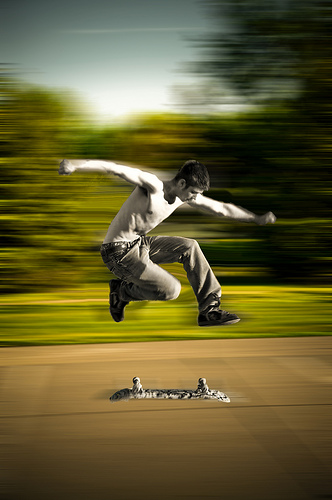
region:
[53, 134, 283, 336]
A male athlete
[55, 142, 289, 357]
A male jumping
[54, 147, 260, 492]
A skateboarder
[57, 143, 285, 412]
A skateboarder doing a trick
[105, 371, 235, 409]
A skateboard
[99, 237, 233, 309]
The jeans the man is wearing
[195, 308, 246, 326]
The left foot of the man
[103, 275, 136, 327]
The right foot of the man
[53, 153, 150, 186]
The right arm of the man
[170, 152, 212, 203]
The head of the skateboarder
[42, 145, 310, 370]
this is a unique photo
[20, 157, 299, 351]
the background makes this picture look alive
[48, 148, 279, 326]
this young man is posing over a skateboard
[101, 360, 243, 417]
the skateboard is turned upside down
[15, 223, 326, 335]
green and yellow scenery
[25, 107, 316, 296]
the green and yellow streaks are grass and trees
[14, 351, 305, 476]
this brown area is the ground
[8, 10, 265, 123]
this part of the photo is the sky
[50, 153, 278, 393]
this skateboarder is not wearing a shirt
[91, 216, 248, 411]
he is doing stunt tricks on his skateboard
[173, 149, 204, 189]
boy has dark hair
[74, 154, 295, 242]
boy has arms extended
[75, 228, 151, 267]
boy wears black belt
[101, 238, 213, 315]
boy is wearing jeans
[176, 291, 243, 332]
boy wears dark shoes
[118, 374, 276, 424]
boy jumps off skateboard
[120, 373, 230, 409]
skateboard is upside down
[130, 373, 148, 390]
skateboard has light colored wheels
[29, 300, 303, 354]
green grass behind boy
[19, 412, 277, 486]
brown dirt under skateboard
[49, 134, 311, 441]
a skateboarder in the air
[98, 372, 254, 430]
an upside down skateboard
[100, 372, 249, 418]
a black and white skateboard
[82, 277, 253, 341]
black shoes worn by skatboarder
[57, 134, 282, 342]
a guy with no shirt on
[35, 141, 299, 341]
a guy doing tricks on a skateboard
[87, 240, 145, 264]
a black belt on his jeans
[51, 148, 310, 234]
arms stretched out at his sides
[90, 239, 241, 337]
black jeans and black shoes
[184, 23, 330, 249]
a blurred tree behind skater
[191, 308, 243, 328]
man wearing black sneakers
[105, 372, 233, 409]
upside down skateboard in air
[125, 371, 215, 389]
wheels under skate in air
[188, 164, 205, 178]
hair on boys head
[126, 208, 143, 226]
man wearing no shirt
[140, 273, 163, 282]
man wearing grey jeans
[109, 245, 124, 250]
belt on mans waist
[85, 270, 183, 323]
mans knee bent in air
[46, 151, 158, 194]
mans left arm behind him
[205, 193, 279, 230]
mans right arm infront of him